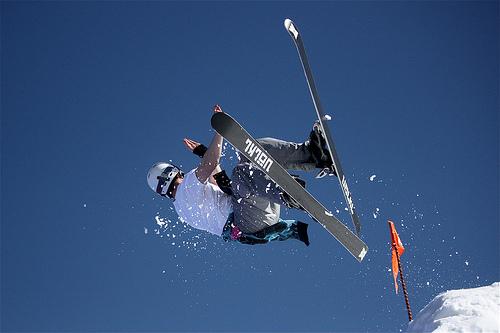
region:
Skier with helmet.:
[137, 128, 243, 232]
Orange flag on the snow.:
[377, 206, 431, 330]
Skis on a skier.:
[192, 29, 446, 259]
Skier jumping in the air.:
[127, 40, 378, 290]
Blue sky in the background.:
[34, 28, 131, 146]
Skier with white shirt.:
[128, 157, 295, 245]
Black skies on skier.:
[209, 104, 397, 277]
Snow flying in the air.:
[141, 201, 231, 266]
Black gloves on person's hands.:
[180, 131, 206, 161]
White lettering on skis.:
[237, 130, 272, 176]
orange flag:
[377, 209, 418, 327]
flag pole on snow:
[389, 247, 413, 317]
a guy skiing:
[135, 90, 363, 260]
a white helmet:
[141, 152, 191, 218]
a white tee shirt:
[178, 161, 236, 247]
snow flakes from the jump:
[358, 167, 492, 245]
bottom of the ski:
[213, 113, 373, 260]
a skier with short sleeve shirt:
[142, 113, 248, 244]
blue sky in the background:
[42, 193, 133, 308]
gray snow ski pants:
[235, 109, 295, 238]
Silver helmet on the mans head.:
[143, 160, 180, 205]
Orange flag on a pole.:
[381, 220, 418, 325]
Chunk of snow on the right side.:
[423, 291, 498, 331]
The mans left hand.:
[180, 135, 203, 156]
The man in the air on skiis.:
[144, 38, 375, 256]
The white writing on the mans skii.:
[245, 139, 272, 171]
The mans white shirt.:
[172, 175, 226, 237]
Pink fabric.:
[228, 225, 240, 240]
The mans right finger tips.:
[215, 106, 227, 114]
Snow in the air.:
[141, 206, 174, 265]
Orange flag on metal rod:
[385, 220, 413, 286]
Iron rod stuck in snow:
[381, 256, 426, 323]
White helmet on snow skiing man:
[136, 160, 166, 200]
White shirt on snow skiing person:
[175, 166, 240, 241]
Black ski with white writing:
[201, 110, 362, 252]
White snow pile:
[422, 280, 493, 315]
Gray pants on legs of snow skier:
[236, 185, 276, 230]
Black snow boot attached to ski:
[295, 131, 325, 181]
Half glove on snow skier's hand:
[180, 135, 205, 161]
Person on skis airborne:
[100, 60, 425, 270]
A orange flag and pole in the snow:
[380, 220, 419, 325]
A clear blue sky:
[26, 40, 113, 124]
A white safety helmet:
[139, 152, 184, 194]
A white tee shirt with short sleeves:
[170, 173, 232, 233]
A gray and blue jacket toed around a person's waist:
[227, 221, 313, 249]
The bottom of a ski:
[277, 16, 384, 236]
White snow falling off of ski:
[140, 222, 191, 255]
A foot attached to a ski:
[299, 124, 348, 177]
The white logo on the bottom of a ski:
[238, 135, 280, 172]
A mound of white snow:
[433, 283, 498, 329]